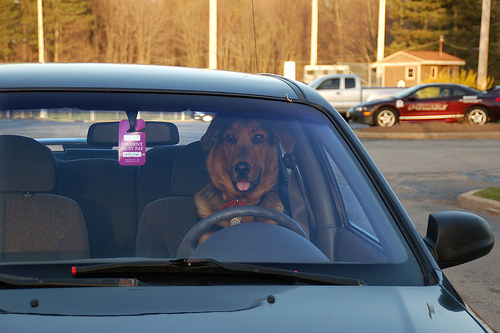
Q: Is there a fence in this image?
A: No, there are no fences.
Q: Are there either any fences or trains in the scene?
A: No, there are no fences or trains.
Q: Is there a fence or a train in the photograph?
A: No, there are no fences or trains.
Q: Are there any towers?
A: No, there are no towers.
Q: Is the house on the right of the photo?
A: Yes, the house is on the right of the image.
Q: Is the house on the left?
A: No, the house is on the right of the image.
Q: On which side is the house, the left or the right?
A: The house is on the right of the image.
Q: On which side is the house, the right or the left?
A: The house is on the right of the image.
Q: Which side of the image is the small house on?
A: The house is on the right of the image.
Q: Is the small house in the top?
A: Yes, the house is in the top of the image.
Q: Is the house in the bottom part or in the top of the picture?
A: The house is in the top of the image.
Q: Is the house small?
A: Yes, the house is small.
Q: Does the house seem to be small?
A: Yes, the house is small.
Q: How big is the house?
A: The house is small.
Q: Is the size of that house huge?
A: No, the house is small.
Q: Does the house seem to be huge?
A: No, the house is small.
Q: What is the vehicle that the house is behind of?
A: The vehicle is a car.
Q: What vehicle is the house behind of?
A: The house is behind the car.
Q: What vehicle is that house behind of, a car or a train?
A: The house is behind a car.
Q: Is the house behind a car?
A: Yes, the house is behind a car.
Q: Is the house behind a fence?
A: No, the house is behind a car.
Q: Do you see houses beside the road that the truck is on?
A: Yes, there is a house beside the road.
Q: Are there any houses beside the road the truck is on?
A: Yes, there is a house beside the road.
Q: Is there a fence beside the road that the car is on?
A: No, there is a house beside the road.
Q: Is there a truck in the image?
A: Yes, there is a truck.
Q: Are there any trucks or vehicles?
A: Yes, there is a truck.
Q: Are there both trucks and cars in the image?
A: Yes, there are both a truck and a car.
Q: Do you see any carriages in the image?
A: No, there are no carriages.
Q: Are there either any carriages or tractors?
A: No, there are no carriages or tractors.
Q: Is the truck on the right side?
A: Yes, the truck is on the right of the image.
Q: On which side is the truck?
A: The truck is on the right of the image.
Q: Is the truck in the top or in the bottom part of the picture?
A: The truck is in the top of the image.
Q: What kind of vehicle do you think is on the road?
A: The vehicle is a truck.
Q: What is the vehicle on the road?
A: The vehicle is a truck.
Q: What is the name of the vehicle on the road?
A: The vehicle is a truck.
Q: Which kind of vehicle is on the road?
A: The vehicle is a truck.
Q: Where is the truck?
A: The truck is on the road.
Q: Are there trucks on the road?
A: Yes, there is a truck on the road.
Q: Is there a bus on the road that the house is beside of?
A: No, there is a truck on the road.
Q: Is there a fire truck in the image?
A: No, there are no fire trucks.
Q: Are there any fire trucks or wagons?
A: No, there are no fire trucks or wagons.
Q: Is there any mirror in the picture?
A: Yes, there is a mirror.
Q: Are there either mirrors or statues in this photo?
A: Yes, there is a mirror.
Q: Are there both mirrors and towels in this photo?
A: No, there is a mirror but no towels.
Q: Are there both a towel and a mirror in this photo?
A: No, there is a mirror but no towels.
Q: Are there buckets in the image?
A: No, there are no buckets.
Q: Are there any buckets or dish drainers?
A: No, there are no buckets or dish drainers.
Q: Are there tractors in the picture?
A: No, there are no tractors.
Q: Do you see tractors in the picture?
A: No, there are no tractors.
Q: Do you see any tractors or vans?
A: No, there are no tractors or vans.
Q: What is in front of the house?
A: The car is in front of the house.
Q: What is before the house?
A: The car is in front of the house.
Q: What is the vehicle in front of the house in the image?
A: The vehicle is a car.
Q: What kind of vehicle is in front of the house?
A: The vehicle is a car.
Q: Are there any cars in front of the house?
A: Yes, there is a car in front of the house.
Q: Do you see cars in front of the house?
A: Yes, there is a car in front of the house.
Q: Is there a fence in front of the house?
A: No, there is a car in front of the house.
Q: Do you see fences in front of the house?
A: No, there is a car in front of the house.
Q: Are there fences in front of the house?
A: No, there is a car in front of the house.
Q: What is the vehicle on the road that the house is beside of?
A: The vehicle is a car.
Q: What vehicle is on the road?
A: The vehicle is a car.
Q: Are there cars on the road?
A: Yes, there is a car on the road.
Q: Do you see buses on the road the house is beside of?
A: No, there is a car on the road.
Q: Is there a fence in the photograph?
A: No, there are no fences.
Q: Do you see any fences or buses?
A: No, there are no fences or buses.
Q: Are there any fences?
A: No, there are no fences.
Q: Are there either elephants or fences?
A: No, there are no fences or elephants.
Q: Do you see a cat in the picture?
A: No, there are no cats.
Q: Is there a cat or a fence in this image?
A: No, there are no cats or fences.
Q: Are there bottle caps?
A: No, there are no bottle caps.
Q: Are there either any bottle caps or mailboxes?
A: No, there are no bottle caps or mailboxes.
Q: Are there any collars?
A: Yes, there is a collar.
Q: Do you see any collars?
A: Yes, there is a collar.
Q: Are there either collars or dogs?
A: Yes, there is a collar.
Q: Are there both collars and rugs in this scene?
A: No, there is a collar but no rugs.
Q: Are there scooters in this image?
A: No, there are no scooters.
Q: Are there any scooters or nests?
A: No, there are no scooters or nests.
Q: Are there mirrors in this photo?
A: Yes, there is a mirror.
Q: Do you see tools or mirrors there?
A: Yes, there is a mirror.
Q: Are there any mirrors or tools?
A: Yes, there is a mirror.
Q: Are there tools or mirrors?
A: Yes, there is a mirror.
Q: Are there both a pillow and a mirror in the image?
A: No, there is a mirror but no pillows.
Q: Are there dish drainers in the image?
A: No, there are no dish drainers.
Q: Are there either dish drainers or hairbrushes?
A: No, there are no dish drainers or hairbrushes.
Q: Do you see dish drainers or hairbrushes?
A: No, there are no dish drainers or hairbrushes.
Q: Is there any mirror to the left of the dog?
A: Yes, there is a mirror to the left of the dog.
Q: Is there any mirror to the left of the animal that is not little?
A: Yes, there is a mirror to the left of the dog.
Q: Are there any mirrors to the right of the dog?
A: No, the mirror is to the left of the dog.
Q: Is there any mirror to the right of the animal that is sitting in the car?
A: No, the mirror is to the left of the dog.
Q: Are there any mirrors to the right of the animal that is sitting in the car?
A: No, the mirror is to the left of the dog.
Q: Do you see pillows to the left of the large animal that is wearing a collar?
A: No, there is a mirror to the left of the dog.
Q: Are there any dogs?
A: Yes, there is a dog.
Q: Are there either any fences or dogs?
A: Yes, there is a dog.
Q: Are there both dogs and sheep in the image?
A: No, there is a dog but no sheep.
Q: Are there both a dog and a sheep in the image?
A: No, there is a dog but no sheep.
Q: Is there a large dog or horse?
A: Yes, there is a large dog.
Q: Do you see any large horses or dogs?
A: Yes, there is a large dog.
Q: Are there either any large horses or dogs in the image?
A: Yes, there is a large dog.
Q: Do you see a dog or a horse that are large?
A: Yes, the dog is large.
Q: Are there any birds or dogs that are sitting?
A: Yes, the dog is sitting.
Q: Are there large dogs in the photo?
A: Yes, there is a large dog.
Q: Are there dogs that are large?
A: Yes, there is a dog that is large.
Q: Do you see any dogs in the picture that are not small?
A: Yes, there is a large dog.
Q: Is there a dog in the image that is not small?
A: Yes, there is a large dog.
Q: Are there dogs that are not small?
A: Yes, there is a large dog.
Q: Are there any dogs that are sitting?
A: Yes, there is a dog that is sitting.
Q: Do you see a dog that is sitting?
A: Yes, there is a dog that is sitting.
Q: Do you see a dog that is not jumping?
A: Yes, there is a dog that is sitting .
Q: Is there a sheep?
A: No, there is no sheep.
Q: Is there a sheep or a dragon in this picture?
A: No, there are no sheep or dragons.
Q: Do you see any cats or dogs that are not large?
A: No, there is a dog but it is large.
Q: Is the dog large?
A: Yes, the dog is large.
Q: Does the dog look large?
A: Yes, the dog is large.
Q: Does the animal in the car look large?
A: Yes, the dog is large.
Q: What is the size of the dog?
A: The dog is large.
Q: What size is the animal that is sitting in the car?
A: The dog is large.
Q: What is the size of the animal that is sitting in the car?
A: The dog is large.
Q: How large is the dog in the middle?
A: The dog is large.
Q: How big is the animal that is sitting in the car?
A: The dog is large.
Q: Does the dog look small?
A: No, the dog is large.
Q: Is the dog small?
A: No, the dog is large.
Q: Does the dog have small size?
A: No, the dog is large.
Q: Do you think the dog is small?
A: No, the dog is large.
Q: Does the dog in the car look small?
A: No, the dog is large.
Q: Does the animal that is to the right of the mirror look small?
A: No, the dog is large.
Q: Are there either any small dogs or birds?
A: No, there is a dog but it is large.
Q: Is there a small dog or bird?
A: No, there is a dog but it is large.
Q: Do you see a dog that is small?
A: No, there is a dog but it is large.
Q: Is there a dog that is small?
A: No, there is a dog but it is large.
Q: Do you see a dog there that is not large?
A: No, there is a dog but it is large.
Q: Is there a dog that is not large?
A: No, there is a dog but it is large.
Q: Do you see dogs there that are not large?
A: No, there is a dog but it is large.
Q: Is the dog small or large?
A: The dog is large.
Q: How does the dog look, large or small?
A: The dog is large.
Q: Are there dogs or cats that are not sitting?
A: No, there is a dog but it is sitting.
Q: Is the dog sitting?
A: Yes, the dog is sitting.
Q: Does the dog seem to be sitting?
A: Yes, the dog is sitting.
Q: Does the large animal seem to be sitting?
A: Yes, the dog is sitting.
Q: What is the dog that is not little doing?
A: The dog is sitting.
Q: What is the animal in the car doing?
A: The dog is sitting.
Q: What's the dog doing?
A: The dog is sitting.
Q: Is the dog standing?
A: No, the dog is sitting.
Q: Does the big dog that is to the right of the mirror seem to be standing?
A: No, the dog is sitting.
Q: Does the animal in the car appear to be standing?
A: No, the dog is sitting.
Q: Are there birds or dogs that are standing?
A: No, there is a dog but it is sitting.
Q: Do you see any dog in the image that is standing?
A: No, there is a dog but it is sitting.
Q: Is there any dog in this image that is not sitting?
A: No, there is a dog but it is sitting.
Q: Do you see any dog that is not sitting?
A: No, there is a dog but it is sitting.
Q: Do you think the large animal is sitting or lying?
A: The dog is sitting.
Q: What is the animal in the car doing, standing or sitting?
A: The dog is sitting.